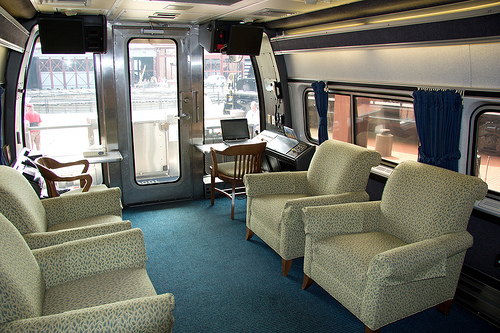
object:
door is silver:
[111, 26, 194, 200]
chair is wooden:
[210, 143, 269, 218]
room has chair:
[1, 0, 500, 331]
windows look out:
[19, 20, 499, 214]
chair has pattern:
[0, 206, 174, 333]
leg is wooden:
[229, 179, 235, 221]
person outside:
[22, 105, 42, 151]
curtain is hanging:
[412, 86, 463, 174]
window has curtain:
[301, 82, 327, 146]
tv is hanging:
[36, 17, 111, 58]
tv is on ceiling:
[191, 14, 264, 60]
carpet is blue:
[122, 192, 499, 332]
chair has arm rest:
[109, 174, 392, 332]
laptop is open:
[220, 119, 261, 146]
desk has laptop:
[196, 119, 267, 173]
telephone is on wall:
[271, 81, 282, 128]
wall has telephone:
[256, 28, 283, 130]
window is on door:
[127, 37, 181, 186]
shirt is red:
[24, 110, 43, 125]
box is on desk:
[82, 147, 108, 157]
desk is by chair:
[32, 147, 124, 191]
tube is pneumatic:
[144, 30, 165, 35]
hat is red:
[25, 104, 33, 107]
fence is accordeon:
[36, 58, 95, 89]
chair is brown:
[34, 153, 93, 198]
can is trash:
[374, 133, 393, 156]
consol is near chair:
[240, 130, 314, 173]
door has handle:
[172, 113, 189, 120]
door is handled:
[176, 113, 192, 118]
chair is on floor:
[305, 159, 487, 330]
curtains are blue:
[312, 79, 464, 175]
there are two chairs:
[0, 164, 176, 332]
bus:
[2, 5, 494, 330]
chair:
[202, 136, 265, 221]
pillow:
[217, 160, 258, 177]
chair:
[32, 153, 95, 198]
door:
[111, 24, 196, 207]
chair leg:
[280, 258, 292, 277]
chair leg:
[245, 226, 254, 240]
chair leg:
[303, 272, 316, 290]